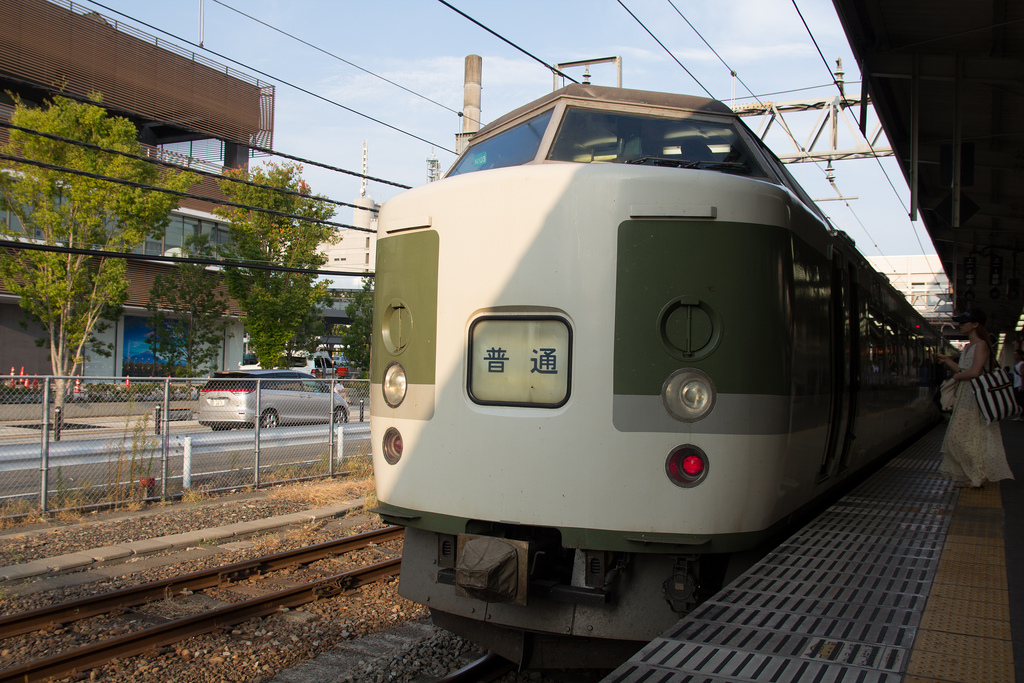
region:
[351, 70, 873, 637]
train at the station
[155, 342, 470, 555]
gold van passing train station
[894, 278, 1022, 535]
trendy woman in dress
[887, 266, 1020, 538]
trendy woman in ball cap and dress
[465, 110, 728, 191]
the windows on the front of the train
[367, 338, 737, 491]
lights on the front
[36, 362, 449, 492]
the chain linked fence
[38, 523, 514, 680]
the empty train tracks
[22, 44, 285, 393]
the building beside the van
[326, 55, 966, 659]
the train is tan and green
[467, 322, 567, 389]
Chinese letters on front a train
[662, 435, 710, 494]
the light is red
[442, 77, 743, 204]
front windows of train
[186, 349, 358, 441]
the car is brown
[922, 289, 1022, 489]
woman wearing a dress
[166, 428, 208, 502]
pole is color gray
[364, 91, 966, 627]
olive green and white electric train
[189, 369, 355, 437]
a silver station wagon on the road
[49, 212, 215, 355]
green leaves on the tree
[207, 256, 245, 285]
green leaves on the tree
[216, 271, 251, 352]
green leaves on the tree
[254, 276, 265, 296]
green leaves on the tree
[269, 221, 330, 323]
green leaves on the tree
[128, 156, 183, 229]
green leaves on the tree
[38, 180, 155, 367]
green leaves on the tree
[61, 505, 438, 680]
train tracks are brown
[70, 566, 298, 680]
brown ballast under tracks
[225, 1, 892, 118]
power lines over train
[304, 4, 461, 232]
white clouds in sky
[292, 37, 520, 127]
thin clouds in sky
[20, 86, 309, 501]
green trees outside tracks